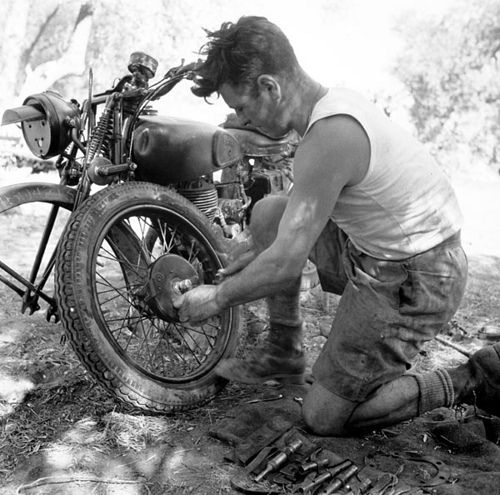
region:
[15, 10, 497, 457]
man fixing the wheel of the bike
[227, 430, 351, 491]
tools on the ground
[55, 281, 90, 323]
treads on the tire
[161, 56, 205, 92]
handle bar on the bike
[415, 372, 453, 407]
sock on the man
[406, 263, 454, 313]
pocket on the back shorts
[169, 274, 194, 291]
screw on the tire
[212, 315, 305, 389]
black boot on the foot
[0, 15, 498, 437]
man repairing old motorcycle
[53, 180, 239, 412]
man holding worn motorcycle tire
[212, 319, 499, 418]
man wearing dusty work boots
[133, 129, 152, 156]
dent in motorcycle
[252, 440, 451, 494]
tools placed on ground next to man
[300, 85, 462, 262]
man wearing white tank top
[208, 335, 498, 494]
man kneeling on blanket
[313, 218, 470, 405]
man wearing shorts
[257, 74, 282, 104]
man has an ear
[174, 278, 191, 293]
metal bold in middle of wheel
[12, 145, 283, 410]
This is a wheel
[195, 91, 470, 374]
The man is dirty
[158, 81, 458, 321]
This is a picture of men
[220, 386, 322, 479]
These are metal tools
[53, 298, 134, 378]
This is a tire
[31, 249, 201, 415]
The tire is rubber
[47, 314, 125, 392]
The tire is black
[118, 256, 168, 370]
These are metal spikes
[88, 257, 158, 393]
The spikes are silver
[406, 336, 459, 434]
These are rolled socks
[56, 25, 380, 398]
a man repairing a motor bike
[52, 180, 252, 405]
the motor bikes front tire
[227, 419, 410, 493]
the mans tools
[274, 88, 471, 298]
the man is wearing a sleeveless shirt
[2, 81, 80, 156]
the motor bikes headlight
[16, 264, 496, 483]
the man is repairing the bike in the shade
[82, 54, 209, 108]
the motor bikes handle bars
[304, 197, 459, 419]
the man is wearing shorts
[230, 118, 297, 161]
a portion of the bikes seat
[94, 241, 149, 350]
the tires spokes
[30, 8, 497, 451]
a man fixing a wheel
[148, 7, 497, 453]
man wears a white tank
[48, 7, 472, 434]
man is holding a tire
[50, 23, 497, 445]
a tire in front a man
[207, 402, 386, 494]
tools are on the ground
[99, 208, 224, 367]
spokes of a wheel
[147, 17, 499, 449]
man is kneeling on the ground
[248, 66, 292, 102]
an ear of a man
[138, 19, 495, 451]
man wears shorts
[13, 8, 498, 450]
a motorcycle behind a man